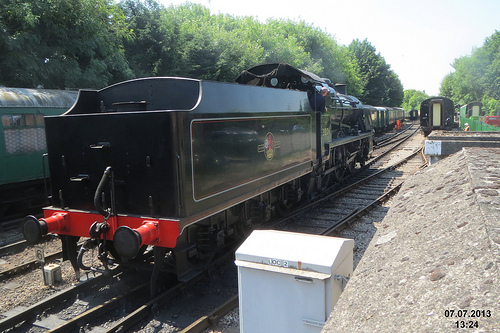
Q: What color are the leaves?
A: Green.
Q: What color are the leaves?
A: Green.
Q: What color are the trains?
A: Black.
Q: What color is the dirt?
A: Brown.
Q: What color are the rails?
A: Gray.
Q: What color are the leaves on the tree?
A: Green.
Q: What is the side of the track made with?
A: Concrete.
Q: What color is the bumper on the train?
A: Red.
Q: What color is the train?
A: Black and red.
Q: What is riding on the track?
A: A train.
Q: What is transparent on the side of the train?
A: A window.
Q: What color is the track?
A: Black.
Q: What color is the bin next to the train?
A: White.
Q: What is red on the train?
A: The bumper.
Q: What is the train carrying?
A: Passengers.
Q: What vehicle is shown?
A: Train.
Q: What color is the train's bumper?
A: Red.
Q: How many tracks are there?
A: Four.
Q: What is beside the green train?
A: Trees.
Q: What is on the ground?
A: Gravel.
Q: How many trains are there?
A: Three.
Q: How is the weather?
A: Sunny.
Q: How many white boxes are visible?
A: One.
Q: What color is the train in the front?
A: Black.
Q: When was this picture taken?
A: Daytime.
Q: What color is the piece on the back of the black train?
A: Red.